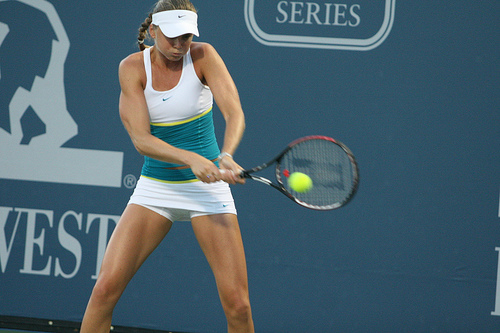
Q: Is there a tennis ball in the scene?
A: Yes, there is a tennis ball.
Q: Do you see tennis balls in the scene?
A: Yes, there is a tennis ball.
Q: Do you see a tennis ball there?
A: Yes, there is a tennis ball.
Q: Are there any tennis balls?
A: Yes, there is a tennis ball.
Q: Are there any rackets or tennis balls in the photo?
A: Yes, there is a tennis ball.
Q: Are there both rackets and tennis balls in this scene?
A: Yes, there are both a tennis ball and a racket.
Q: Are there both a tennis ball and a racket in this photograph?
A: Yes, there are both a tennis ball and a racket.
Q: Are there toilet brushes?
A: No, there are no toilet brushes.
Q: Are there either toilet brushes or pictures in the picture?
A: No, there are no toilet brushes or pictures.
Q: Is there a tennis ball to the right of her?
A: Yes, there is a tennis ball to the right of the woman.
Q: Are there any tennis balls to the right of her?
A: Yes, there is a tennis ball to the right of the woman.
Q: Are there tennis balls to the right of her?
A: Yes, there is a tennis ball to the right of the woman.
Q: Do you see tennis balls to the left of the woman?
A: No, the tennis ball is to the right of the woman.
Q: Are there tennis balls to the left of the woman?
A: No, the tennis ball is to the right of the woman.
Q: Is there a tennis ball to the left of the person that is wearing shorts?
A: No, the tennis ball is to the right of the woman.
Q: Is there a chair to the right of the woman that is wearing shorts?
A: No, there is a tennis ball to the right of the woman.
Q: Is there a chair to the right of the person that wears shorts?
A: No, there is a tennis ball to the right of the woman.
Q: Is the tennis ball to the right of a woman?
A: Yes, the tennis ball is to the right of a woman.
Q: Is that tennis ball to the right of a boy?
A: No, the tennis ball is to the right of a woman.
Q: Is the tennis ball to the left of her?
A: No, the tennis ball is to the right of a woman.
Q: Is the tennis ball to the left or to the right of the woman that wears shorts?
A: The tennis ball is to the right of the woman.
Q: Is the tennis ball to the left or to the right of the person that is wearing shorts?
A: The tennis ball is to the right of the woman.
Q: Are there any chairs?
A: No, there are no chairs.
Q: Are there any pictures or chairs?
A: No, there are no chairs or pictures.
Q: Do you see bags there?
A: No, there are no bags.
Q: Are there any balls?
A: Yes, there is a ball.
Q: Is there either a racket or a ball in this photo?
A: Yes, there is a ball.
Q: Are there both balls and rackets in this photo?
A: Yes, there are both a ball and a racket.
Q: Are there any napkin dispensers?
A: No, there are no napkin dispensers.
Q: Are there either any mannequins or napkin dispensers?
A: No, there are no napkin dispensers or mannequins.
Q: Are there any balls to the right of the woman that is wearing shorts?
A: Yes, there is a ball to the right of the woman.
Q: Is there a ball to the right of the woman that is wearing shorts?
A: Yes, there is a ball to the right of the woman.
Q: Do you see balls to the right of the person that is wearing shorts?
A: Yes, there is a ball to the right of the woman.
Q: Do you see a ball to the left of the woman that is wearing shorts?
A: No, the ball is to the right of the woman.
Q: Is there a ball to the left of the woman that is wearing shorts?
A: No, the ball is to the right of the woman.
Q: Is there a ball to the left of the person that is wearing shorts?
A: No, the ball is to the right of the woman.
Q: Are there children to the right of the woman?
A: No, there is a ball to the right of the woman.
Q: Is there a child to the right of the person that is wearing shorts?
A: No, there is a ball to the right of the woman.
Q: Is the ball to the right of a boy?
A: No, the ball is to the right of the woman.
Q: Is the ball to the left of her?
A: No, the ball is to the right of the woman.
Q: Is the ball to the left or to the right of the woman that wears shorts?
A: The ball is to the right of the woman.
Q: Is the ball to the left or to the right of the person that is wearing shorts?
A: The ball is to the right of the woman.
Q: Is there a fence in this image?
A: No, there are no fences.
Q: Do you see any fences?
A: No, there are no fences.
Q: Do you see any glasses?
A: No, there are no glasses.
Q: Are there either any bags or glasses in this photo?
A: No, there are no glasses or bags.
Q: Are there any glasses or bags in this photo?
A: No, there are no glasses or bags.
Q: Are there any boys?
A: No, there are no boys.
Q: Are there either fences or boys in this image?
A: No, there are no boys or fences.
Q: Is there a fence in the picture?
A: No, there are no fences.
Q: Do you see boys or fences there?
A: No, there are no fences or boys.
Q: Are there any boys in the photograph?
A: No, there are no boys.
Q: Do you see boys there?
A: No, there are no boys.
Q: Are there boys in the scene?
A: No, there are no boys.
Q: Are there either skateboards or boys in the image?
A: No, there are no boys or skateboards.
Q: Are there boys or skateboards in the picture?
A: No, there are no boys or skateboards.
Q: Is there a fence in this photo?
A: No, there are no fences.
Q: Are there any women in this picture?
A: Yes, there is a woman.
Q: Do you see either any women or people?
A: Yes, there is a woman.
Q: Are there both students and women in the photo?
A: No, there is a woman but no students.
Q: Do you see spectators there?
A: No, there are no spectators.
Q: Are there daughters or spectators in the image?
A: No, there are no spectators or daughters.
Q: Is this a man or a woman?
A: This is a woman.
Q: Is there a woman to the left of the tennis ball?
A: Yes, there is a woman to the left of the tennis ball.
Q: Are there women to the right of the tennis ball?
A: No, the woman is to the left of the tennis ball.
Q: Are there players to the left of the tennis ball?
A: No, there is a woman to the left of the tennis ball.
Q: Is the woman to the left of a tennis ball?
A: Yes, the woman is to the left of a tennis ball.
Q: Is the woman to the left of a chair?
A: No, the woman is to the left of a tennis ball.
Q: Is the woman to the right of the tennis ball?
A: No, the woman is to the left of the tennis ball.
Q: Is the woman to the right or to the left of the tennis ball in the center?
A: The woman is to the left of the tennis ball.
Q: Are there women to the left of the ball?
A: Yes, there is a woman to the left of the ball.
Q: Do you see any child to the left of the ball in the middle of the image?
A: No, there is a woman to the left of the ball.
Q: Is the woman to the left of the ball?
A: Yes, the woman is to the left of the ball.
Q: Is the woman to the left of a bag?
A: No, the woman is to the left of the ball.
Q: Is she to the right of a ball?
A: No, the woman is to the left of a ball.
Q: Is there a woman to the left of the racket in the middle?
A: Yes, there is a woman to the left of the racket.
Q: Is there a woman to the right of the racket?
A: No, the woman is to the left of the racket.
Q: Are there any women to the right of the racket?
A: No, the woman is to the left of the racket.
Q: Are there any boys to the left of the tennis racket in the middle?
A: No, there is a woman to the left of the tennis racket.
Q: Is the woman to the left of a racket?
A: Yes, the woman is to the left of a racket.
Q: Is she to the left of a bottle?
A: No, the woman is to the left of a racket.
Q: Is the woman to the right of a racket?
A: No, the woman is to the left of a racket.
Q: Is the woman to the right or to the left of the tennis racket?
A: The woman is to the left of the tennis racket.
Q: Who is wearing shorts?
A: The woman is wearing shorts.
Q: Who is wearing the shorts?
A: The woman is wearing shorts.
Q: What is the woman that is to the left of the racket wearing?
A: The woman is wearing shorts.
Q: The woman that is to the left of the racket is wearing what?
A: The woman is wearing shorts.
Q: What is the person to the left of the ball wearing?
A: The woman is wearing shorts.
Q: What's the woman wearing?
A: The woman is wearing shorts.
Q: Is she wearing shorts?
A: Yes, the woman is wearing shorts.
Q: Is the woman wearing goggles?
A: No, the woman is wearing shorts.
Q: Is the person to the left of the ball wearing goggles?
A: No, the woman is wearing shorts.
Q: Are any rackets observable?
A: Yes, there is a racket.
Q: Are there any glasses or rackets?
A: Yes, there is a racket.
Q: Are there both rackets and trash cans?
A: No, there is a racket but no trash cans.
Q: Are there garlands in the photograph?
A: No, there are no garlands.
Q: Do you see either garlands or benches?
A: No, there are no garlands or benches.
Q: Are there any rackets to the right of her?
A: Yes, there is a racket to the right of the woman.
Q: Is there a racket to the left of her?
A: No, the racket is to the right of the woman.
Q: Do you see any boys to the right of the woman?
A: No, there is a racket to the right of the woman.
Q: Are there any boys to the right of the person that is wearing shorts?
A: No, there is a racket to the right of the woman.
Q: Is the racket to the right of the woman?
A: Yes, the racket is to the right of the woman.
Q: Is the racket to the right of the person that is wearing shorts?
A: Yes, the racket is to the right of the woman.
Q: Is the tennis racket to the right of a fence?
A: No, the tennis racket is to the right of the woman.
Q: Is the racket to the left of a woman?
A: No, the racket is to the right of a woman.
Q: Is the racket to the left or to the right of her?
A: The racket is to the right of the woman.